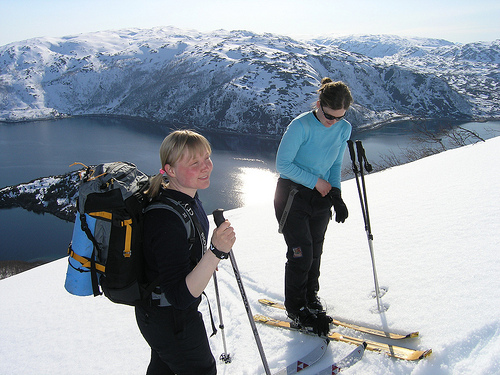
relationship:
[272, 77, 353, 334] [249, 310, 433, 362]
woman standing on ski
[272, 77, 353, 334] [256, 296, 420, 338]
woman standing on ski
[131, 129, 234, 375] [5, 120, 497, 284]
woman standing in front of lake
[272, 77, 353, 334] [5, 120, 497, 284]
woman standing in front of lake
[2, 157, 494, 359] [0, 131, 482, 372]
snow covering ground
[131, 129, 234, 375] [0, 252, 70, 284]
woman standing in front of ledge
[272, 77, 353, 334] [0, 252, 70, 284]
woman standing in front of ledge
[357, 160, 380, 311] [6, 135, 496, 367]
pole stuck in snow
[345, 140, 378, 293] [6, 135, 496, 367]
ski pole stuck in snow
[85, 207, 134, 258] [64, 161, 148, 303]
strap tightening backpack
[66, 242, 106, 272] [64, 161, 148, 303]
strap tightening backpack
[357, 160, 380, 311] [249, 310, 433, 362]
pole standing next to ski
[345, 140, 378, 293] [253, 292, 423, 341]
ski pole standing next to ski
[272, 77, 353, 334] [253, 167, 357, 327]
woman wearing jeans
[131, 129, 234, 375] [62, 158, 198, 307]
woman carrying backpack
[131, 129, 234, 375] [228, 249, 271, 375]
woman holding pole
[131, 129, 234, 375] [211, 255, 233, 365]
woman holding stick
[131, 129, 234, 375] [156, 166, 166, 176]
woman wearing band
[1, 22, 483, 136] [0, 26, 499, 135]
snow covering mountain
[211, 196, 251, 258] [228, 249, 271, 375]
handle attached to pole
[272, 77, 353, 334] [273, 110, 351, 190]
woman wearing shirt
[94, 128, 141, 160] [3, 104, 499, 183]
water of lake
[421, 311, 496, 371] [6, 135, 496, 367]
tracks in snow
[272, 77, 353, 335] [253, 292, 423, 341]
woman on ski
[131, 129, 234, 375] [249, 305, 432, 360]
woman on ski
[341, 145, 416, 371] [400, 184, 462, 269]
pole in snow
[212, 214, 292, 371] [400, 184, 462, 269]
pole in snow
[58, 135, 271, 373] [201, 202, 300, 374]
woman on silver skis